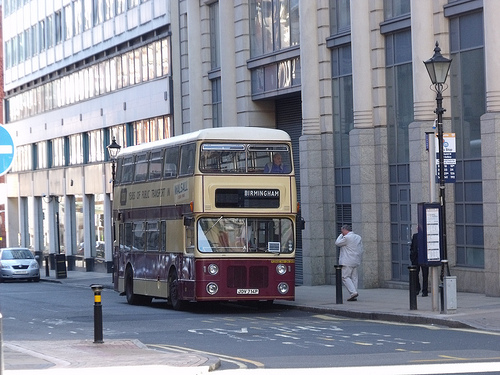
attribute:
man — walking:
[332, 220, 366, 302]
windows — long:
[85, 139, 282, 309]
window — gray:
[251, 55, 302, 97]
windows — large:
[148, 172, 374, 329]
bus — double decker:
[113, 142, 308, 316]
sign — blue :
[2, 121, 23, 183]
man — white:
[304, 209, 435, 334]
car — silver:
[1, 248, 39, 284]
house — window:
[209, 15, 497, 290]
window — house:
[247, 63, 268, 98]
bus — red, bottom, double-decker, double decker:
[110, 122, 300, 302]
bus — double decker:
[105, 122, 304, 314]